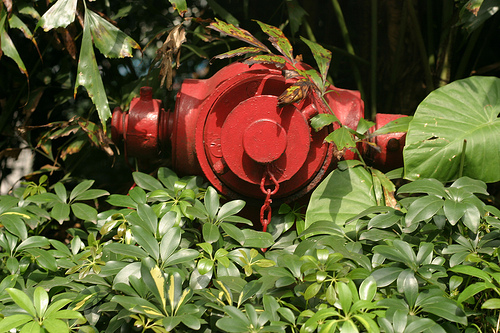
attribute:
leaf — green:
[332, 280, 354, 317]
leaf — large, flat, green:
[401, 74, 498, 186]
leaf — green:
[398, 177, 453, 197]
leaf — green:
[443, 197, 467, 224]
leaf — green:
[448, 177, 488, 192]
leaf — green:
[416, 242, 432, 259]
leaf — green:
[365, 210, 402, 227]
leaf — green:
[394, 179, 451, 201]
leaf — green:
[366, 236, 416, 271]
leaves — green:
[32, 177, 106, 227]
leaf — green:
[219, 196, 246, 216]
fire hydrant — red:
[101, 53, 423, 223]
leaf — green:
[234, 191, 491, 298]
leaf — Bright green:
[160, 222, 186, 270]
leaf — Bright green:
[102, 237, 153, 263]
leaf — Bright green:
[29, 280, 49, 317]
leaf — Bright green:
[112, 292, 154, 314]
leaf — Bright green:
[215, 249, 231, 267]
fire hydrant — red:
[111, 50, 414, 253]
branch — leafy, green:
[206, 14, 371, 154]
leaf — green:
[371, 267, 400, 286]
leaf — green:
[401, 272, 420, 309]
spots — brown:
[282, 90, 307, 102]